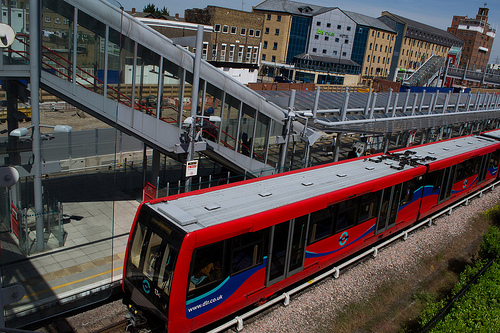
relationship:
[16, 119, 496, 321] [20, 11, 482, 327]
paved platform on station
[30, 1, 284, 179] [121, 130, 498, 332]
staircase behind train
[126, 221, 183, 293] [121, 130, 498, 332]
window on train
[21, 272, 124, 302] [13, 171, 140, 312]
line on platform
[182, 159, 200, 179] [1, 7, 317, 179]
sign below staircase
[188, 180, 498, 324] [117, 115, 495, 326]
rail next to subway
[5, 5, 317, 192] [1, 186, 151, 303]
stairs next to platform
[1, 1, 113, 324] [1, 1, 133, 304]
glass wall at platform